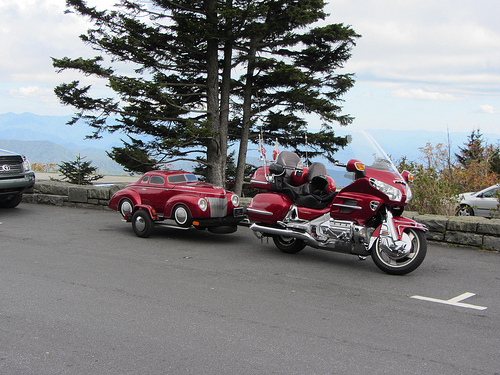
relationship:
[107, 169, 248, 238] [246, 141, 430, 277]
car behind bike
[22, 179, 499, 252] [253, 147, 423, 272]
fence behind bike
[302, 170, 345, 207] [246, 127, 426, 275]
helmet on bike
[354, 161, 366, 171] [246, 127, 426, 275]
indicator of bike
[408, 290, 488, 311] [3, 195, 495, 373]
white mark on road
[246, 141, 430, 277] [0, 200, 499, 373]
bike parked on paved street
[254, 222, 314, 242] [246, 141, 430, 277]
exhaust on bike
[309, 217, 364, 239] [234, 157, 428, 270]
engine on motorcycle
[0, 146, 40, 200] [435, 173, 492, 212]
front end of car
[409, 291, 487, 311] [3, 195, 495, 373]
lines painted on road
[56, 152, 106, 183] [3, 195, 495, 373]
bush on side of road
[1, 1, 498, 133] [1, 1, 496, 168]
clouds in sky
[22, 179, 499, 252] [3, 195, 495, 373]
fence on side of road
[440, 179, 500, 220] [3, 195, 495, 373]
car on opposite road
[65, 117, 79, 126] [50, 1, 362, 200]
leaf on tree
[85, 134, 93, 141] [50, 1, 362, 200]
leaf on tree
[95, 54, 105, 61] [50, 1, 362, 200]
leaf on tree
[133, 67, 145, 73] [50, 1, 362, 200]
leaf on tree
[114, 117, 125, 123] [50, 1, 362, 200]
leaf on tree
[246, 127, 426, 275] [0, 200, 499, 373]
bike on paved street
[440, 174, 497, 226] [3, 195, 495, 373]
car off road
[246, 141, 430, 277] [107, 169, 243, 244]
bike pulling a car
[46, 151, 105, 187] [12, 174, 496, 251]
tree behind a wall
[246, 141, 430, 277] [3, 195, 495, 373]
bike parked in road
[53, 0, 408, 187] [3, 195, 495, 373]
tree next to road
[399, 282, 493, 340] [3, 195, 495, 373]
lines on road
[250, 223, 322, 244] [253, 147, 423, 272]
silencer of bike